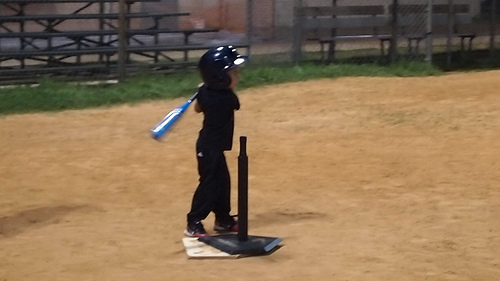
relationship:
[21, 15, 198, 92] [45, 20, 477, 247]
bleachers on field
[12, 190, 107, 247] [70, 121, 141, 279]
shadow on ground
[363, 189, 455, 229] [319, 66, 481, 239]
prints in dirt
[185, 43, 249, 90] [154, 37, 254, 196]
helmet on boy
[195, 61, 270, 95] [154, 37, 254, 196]
head on boy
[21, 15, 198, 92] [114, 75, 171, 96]
bleachers behind grass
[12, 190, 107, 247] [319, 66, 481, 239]
shadow on dirt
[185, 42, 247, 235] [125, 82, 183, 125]
boy holding bat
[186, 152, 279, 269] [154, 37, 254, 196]
pants on boy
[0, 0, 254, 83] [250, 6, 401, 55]
bleachers for fans